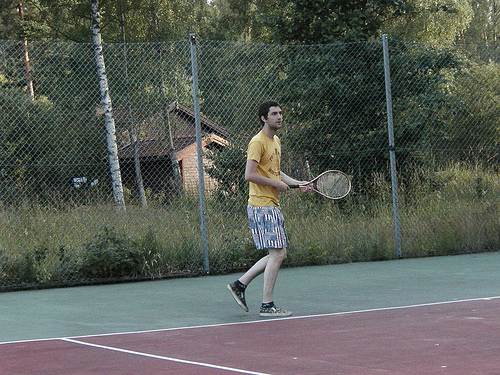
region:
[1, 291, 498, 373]
red tennis court with white markings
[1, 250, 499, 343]
green out of bounds area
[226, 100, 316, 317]
teenager with short brown hair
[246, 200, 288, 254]
multi colored striped shorts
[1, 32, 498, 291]
tall chain link fence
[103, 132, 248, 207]
smaller brown building in the background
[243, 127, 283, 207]
yellow short sleeved t-shirt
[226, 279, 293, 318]
multi colored slip on shoes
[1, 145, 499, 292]
tall green grass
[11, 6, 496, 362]
A young man playing tennis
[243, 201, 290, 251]
Pair of blue and white shorts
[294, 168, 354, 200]
A tennis racket in a man's hand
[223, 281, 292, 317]
Pair of black and white high-top sneakers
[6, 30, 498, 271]
A metal chain-link fence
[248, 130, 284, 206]
A yellow and red t-shirt with an anchor on the front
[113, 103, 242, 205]
A small brown house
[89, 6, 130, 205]
A tall tree next to a house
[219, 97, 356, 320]
A young man holding a tennis racket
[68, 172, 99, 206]
Mailbox next to a brown house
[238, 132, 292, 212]
The man has on a yellow shirt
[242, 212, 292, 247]
The man has on colorful pants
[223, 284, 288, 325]
The man is wearing colorful shoes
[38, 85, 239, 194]
The house behind the fence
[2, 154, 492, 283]
The grass is growing wild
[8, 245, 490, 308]
The green area of the court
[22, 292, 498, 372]
The red area of the court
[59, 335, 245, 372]
The white line on the court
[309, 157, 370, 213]
The man is holding a racket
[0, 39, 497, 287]
a green chain-link fence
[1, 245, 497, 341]
green section of tennis court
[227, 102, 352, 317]
guy holding a tennis racket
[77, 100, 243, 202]
small, brown building in the background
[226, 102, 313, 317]
guy wearing a yellow t-shirt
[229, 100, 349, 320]
a guy playing tennis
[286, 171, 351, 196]
a brown tennis racket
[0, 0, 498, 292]
green trees and grass surround the building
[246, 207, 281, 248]
pattern on the shorts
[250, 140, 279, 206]
the shirt is golden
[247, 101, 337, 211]
man holding the racket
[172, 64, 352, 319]
fence behind the man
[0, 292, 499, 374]
red portion of tennis court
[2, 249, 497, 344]
green pavement on outer rim of tennis court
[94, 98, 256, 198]
small brown building behind the fence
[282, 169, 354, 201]
brown tennis racket with black handle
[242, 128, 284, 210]
yellow shirt with red letters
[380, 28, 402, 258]
tall thin metal pole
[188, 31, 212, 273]
tall thin metal pole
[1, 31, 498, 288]
silver metal chain link fence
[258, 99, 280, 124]
short black hair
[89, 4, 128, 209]
tall fwhite and black tree trunk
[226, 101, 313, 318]
man playing tennis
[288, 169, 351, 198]
tennis racquet with black grip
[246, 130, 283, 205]
yellow short-sleeved tee shirt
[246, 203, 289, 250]
patterned shorts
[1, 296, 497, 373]
the in bounds part of the tennis court is red